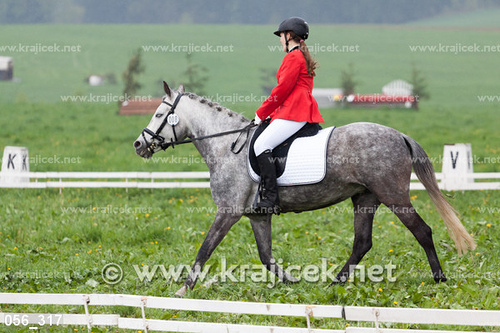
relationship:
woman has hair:
[247, 16, 328, 213] [299, 34, 326, 70]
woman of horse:
[247, 16, 328, 213] [137, 94, 472, 285]